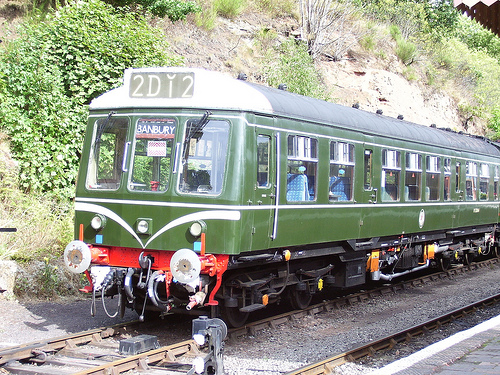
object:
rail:
[0, 255, 500, 375]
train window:
[83, 115, 129, 190]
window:
[175, 116, 228, 200]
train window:
[286, 155, 319, 205]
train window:
[327, 160, 354, 204]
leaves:
[53, 155, 65, 160]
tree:
[0, 0, 187, 199]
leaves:
[65, 54, 76, 62]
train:
[61, 66, 500, 330]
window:
[329, 139, 356, 164]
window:
[377, 149, 402, 169]